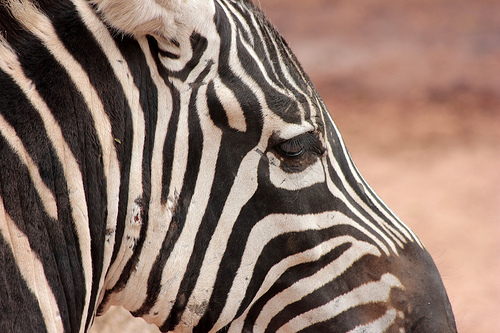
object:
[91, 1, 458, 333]
head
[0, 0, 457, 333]
zebra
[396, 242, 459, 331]
nose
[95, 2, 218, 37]
ear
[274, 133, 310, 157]
eye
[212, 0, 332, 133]
forehead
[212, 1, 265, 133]
stripe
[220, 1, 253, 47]
stripe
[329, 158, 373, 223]
stripe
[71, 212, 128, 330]
wrinkles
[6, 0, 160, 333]
neck area